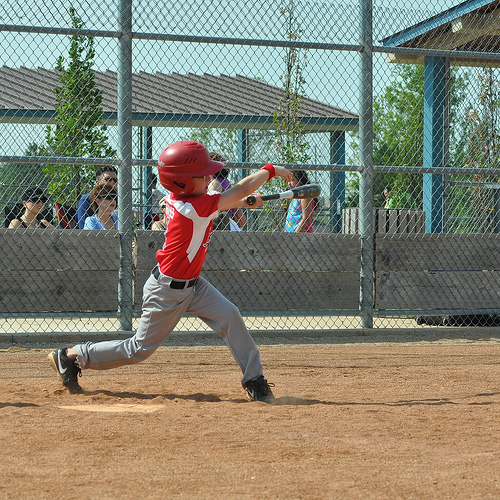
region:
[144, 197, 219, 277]
The boy's shirt is red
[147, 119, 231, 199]
The boy's helmet is red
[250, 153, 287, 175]
The boy's bracelet is red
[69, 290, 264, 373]
The boy's pants are grey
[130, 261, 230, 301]
The boy has a belt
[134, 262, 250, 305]
The boy's belt is black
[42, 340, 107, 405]
The boy's shoes are black and white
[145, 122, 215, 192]
The boy has a helmet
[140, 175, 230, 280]
The boy has a shirt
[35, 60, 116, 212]
The tree is green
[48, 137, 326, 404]
young boy hitting baseball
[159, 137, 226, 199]
batter's helmet on young boy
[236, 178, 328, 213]
little league baseball bat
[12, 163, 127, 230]
people watching baseball game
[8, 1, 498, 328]
chain link fence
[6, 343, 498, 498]
part of baseball diamond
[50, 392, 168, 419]
home plate on baseball field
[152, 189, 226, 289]
red team shirt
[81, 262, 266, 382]
young boy's baseball pants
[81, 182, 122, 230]
woman wearing visor and sunglasses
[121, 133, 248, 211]
The child has a helmet on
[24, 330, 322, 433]
The child is wearing sneakers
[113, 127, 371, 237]
The boy is hitting a ball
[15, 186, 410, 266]
Parents and fans in the back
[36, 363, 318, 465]
A child standing in the dirt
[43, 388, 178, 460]
Baseball plate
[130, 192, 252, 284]
Red uniform on child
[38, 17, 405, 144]
Trees in the back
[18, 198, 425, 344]
A fence in the back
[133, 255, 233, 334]
The child has a belt on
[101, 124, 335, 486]
boy playing baseball in uniform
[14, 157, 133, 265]
adults watching baseball game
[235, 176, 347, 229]
wooden baseball bat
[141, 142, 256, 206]
red safety helmet used in baseball game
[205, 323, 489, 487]
red dirt base ball field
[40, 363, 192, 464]
homelate in base ball game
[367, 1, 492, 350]
side to dug out at baseball game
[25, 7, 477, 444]
security fencing at baseball field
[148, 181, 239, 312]
red and white uniform shirt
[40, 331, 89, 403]
black Nike baseball cleats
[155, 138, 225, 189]
Red helmet on a child.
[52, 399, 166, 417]
Home plate covered in dirt.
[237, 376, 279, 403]
Black and white Nike cleat.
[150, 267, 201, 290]
Black belt on boy.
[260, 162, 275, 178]
Red sweat band on child's wrist.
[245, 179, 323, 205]
Black and white baseball bat.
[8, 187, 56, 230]
Person sitting behind the fence.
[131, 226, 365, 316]
Wooden boards on the fence.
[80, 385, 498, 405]
Shadow of a child playing baseball.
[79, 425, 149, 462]
Dirt on a baseball field.